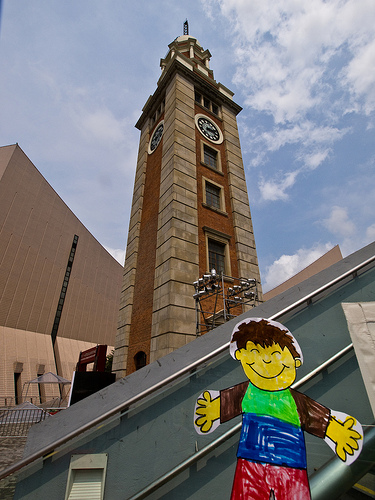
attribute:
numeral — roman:
[207, 131, 213, 139]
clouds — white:
[219, 0, 372, 132]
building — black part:
[0, 144, 124, 404]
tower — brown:
[103, 19, 273, 329]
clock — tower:
[185, 110, 232, 144]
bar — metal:
[51, 233, 80, 396]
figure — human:
[189, 312, 367, 498]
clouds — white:
[5, 3, 374, 294]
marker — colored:
[264, 437, 287, 464]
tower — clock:
[107, 12, 269, 348]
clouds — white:
[199, 1, 374, 293]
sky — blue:
[0, 0, 374, 296]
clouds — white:
[242, 9, 349, 163]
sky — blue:
[271, 192, 303, 252]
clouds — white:
[245, 0, 371, 151]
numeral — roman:
[211, 125, 214, 130]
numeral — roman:
[198, 121, 202, 124]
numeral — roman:
[195, 114, 206, 124]